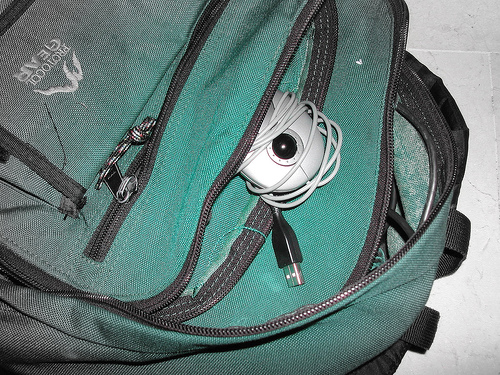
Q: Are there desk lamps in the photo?
A: No, there are no desk lamps.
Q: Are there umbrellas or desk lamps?
A: No, there are no desk lamps or umbrellas.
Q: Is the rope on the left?
A: Yes, the rope is on the left of the image.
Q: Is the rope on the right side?
A: No, the rope is on the left of the image.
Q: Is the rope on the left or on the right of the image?
A: The rope is on the left of the image.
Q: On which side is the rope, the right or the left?
A: The rope is on the left of the image.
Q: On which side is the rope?
A: The rope is on the left of the image.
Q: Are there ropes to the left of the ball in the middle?
A: Yes, there is a rope to the left of the ball.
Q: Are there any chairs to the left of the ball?
A: No, there is a rope to the left of the ball.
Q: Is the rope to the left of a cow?
A: No, the rope is to the left of the ball.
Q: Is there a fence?
A: No, there are no fences.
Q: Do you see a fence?
A: No, there are no fences.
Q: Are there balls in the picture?
A: Yes, there is a ball.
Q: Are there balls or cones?
A: Yes, there is a ball.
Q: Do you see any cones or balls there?
A: Yes, there is a ball.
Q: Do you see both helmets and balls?
A: No, there is a ball but no helmets.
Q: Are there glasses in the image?
A: No, there are no glasses.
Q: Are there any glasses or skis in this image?
A: No, there are no glasses or skis.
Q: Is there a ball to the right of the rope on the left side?
A: Yes, there is a ball to the right of the rope.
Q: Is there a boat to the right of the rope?
A: No, there is a ball to the right of the rope.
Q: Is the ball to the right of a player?
A: No, the ball is to the right of the rope.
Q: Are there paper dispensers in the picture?
A: No, there are no paper dispensers.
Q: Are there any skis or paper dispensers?
A: No, there are no paper dispensers or skis.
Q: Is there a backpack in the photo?
A: Yes, there is a backpack.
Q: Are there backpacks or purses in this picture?
A: Yes, there is a backpack.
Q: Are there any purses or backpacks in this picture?
A: Yes, there is a backpack.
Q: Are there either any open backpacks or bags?
A: Yes, there is an open backpack.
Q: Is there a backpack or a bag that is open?
A: Yes, the backpack is open.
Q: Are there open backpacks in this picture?
A: Yes, there is an open backpack.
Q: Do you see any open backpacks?
A: Yes, there is an open backpack.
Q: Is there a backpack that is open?
A: Yes, there is an open backpack.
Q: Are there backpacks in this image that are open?
A: Yes, there is a backpack that is open.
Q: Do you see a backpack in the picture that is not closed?
A: Yes, there is a open backpack.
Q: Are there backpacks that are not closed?
A: Yes, there is a open backpack.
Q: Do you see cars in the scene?
A: No, there are no cars.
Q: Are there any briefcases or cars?
A: No, there are no cars or briefcases.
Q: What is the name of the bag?
A: The bag is a backpack.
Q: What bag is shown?
A: The bag is a backpack.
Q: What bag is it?
A: The bag is a backpack.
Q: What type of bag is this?
A: This is a backpack.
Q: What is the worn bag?
A: The bag is a backpack.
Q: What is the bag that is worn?
A: The bag is a backpack.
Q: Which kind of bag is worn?
A: The bag is a backpack.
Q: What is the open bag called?
A: The bag is a backpack.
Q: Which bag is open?
A: The bag is a backpack.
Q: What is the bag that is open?
A: The bag is a backpack.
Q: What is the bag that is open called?
A: The bag is a backpack.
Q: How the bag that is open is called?
A: The bag is a backpack.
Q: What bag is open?
A: The bag is a backpack.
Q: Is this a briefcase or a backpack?
A: This is a backpack.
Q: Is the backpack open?
A: Yes, the backpack is open.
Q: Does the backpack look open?
A: Yes, the backpack is open.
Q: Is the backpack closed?
A: No, the backpack is open.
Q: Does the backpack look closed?
A: No, the backpack is open.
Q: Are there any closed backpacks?
A: No, there is a backpack but it is open.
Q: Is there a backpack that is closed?
A: No, there is a backpack but it is open.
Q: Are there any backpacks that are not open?
A: No, there is a backpack but it is open.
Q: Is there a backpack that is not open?
A: No, there is a backpack but it is open.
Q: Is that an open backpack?
A: Yes, that is an open backpack.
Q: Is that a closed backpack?
A: No, that is an open backpack.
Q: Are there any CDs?
A: No, there are no cds.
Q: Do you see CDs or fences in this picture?
A: No, there are no CDs or fences.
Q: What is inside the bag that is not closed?
A: The dirt is inside the backpack.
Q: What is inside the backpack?
A: The dirt is inside the backpack.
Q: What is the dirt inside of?
A: The dirt is inside the backpack.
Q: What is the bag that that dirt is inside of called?
A: The bag is a backpack.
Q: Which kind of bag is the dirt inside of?
A: The dirt is inside the backpack.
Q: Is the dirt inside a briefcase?
A: No, the dirt is inside the backpack.